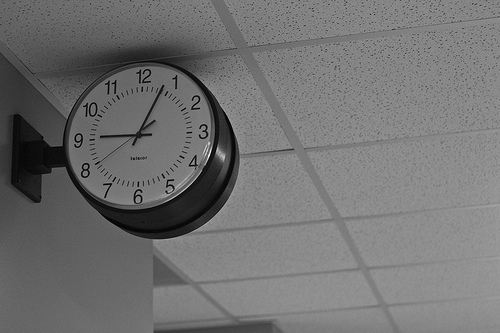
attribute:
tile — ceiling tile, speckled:
[219, 1, 498, 53]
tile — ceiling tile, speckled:
[0, 1, 243, 77]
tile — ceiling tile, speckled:
[242, 13, 500, 151]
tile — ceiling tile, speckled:
[35, 47, 303, 161]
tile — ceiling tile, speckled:
[298, 125, 498, 221]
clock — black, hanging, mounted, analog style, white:
[52, 54, 247, 246]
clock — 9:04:
[66, 77, 178, 222]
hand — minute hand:
[130, 82, 172, 150]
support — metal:
[20, 132, 93, 203]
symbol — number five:
[158, 175, 179, 197]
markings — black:
[65, 119, 123, 207]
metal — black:
[109, 206, 195, 235]